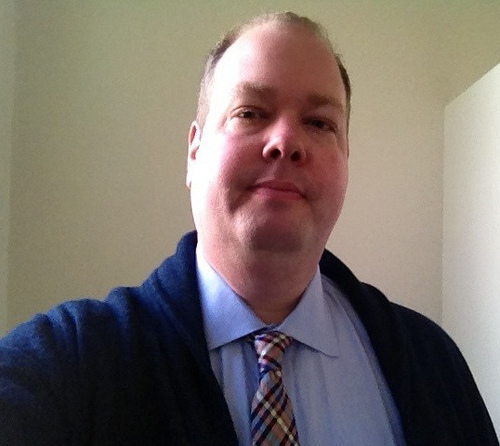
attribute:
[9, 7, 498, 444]
person — male, middle-aged, overweight, dressed, posing, shaven, heavy-set, light-skinned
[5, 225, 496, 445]
sweater — blue, navy blue, black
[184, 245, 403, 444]
shirt — blue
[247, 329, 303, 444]
tie — plaid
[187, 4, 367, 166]
hair — thinning, short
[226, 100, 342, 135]
eyes — dark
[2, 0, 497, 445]
wall — white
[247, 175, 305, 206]
mouth — closed, red